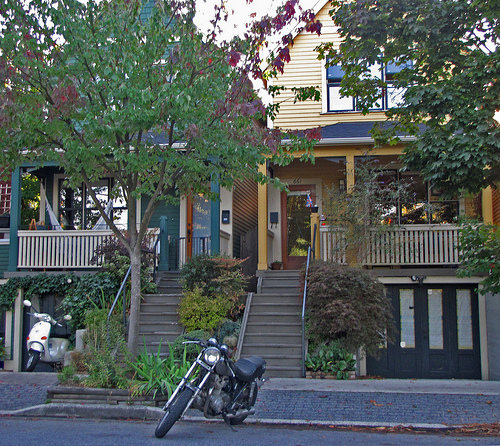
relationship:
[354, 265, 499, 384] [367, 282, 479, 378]
garage has doors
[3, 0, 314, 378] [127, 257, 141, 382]
tree has trunk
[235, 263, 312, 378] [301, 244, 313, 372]
stairs have railing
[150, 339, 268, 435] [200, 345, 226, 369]
motorcycle has headlight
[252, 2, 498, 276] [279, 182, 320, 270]
building has door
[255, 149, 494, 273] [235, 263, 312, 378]
porch has staircase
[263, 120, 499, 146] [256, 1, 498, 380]
roof on home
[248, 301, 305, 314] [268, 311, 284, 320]
stair has part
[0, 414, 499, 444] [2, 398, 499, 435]
road has edge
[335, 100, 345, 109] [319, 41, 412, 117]
part of window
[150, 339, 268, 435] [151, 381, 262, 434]
vehicle has wheels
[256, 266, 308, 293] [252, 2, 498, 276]
steps up to house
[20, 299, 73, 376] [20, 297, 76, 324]
moped has mirrors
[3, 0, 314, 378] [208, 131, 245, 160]
tree has leaves